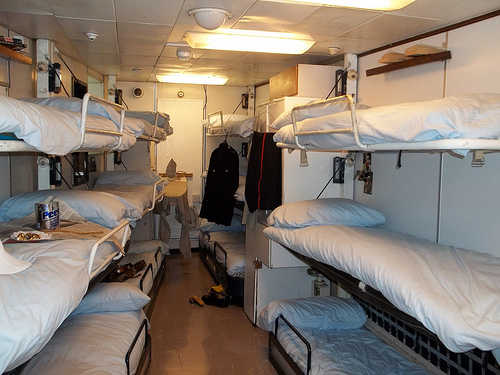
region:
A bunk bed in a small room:
[337, 228, 479, 316]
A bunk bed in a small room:
[375, 106, 465, 148]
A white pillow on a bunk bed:
[298, 204, 365, 218]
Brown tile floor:
[183, 317, 239, 364]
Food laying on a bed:
[15, 229, 55, 246]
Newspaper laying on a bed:
[65, 212, 98, 240]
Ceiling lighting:
[187, 31, 317, 58]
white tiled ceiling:
[105, 14, 163, 58]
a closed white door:
[175, 107, 199, 172]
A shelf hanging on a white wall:
[378, 48, 441, 73]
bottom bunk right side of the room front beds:
[267, 274, 445, 374]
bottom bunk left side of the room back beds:
[199, 227, 246, 279]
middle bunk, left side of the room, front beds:
[263, 172, 496, 334]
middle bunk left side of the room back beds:
[200, 157, 250, 202]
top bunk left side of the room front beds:
[272, 90, 497, 154]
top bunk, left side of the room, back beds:
[203, 106, 268, 133]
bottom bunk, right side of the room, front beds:
[32, 288, 152, 373]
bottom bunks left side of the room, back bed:
[111, 231, 171, 293]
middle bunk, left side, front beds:
[11, 185, 133, 365]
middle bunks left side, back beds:
[94, 165, 169, 224]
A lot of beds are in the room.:
[263, 83, 498, 364]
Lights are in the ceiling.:
[171, 6, 318, 62]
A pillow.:
[262, 185, 401, 237]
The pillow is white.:
[263, 186, 401, 236]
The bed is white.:
[263, 189, 496, 354]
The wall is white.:
[391, 180, 431, 224]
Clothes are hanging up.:
[193, 124, 298, 259]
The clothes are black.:
[176, 113, 299, 235]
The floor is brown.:
[177, 316, 244, 370]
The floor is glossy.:
[173, 316, 238, 369]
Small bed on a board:
[263, 196, 498, 341]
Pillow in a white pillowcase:
[269, 200, 386, 227]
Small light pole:
[156, 72, 228, 89]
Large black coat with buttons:
[194, 133, 240, 224]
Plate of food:
[8, 227, 53, 242]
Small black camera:
[132, 85, 142, 100]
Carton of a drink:
[36, 196, 61, 228]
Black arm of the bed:
[271, 315, 311, 370]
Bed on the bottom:
[264, 296, 436, 372]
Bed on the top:
[273, 95, 499, 155]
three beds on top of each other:
[278, 61, 493, 373]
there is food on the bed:
[0, 220, 52, 247]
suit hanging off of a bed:
[203, 127, 243, 231]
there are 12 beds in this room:
[0, 72, 499, 372]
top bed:
[281, 82, 495, 160]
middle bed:
[264, 177, 493, 321]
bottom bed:
[253, 288, 395, 373]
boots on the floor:
[192, 276, 237, 313]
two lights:
[148, 24, 290, 90]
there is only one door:
[161, 97, 209, 202]